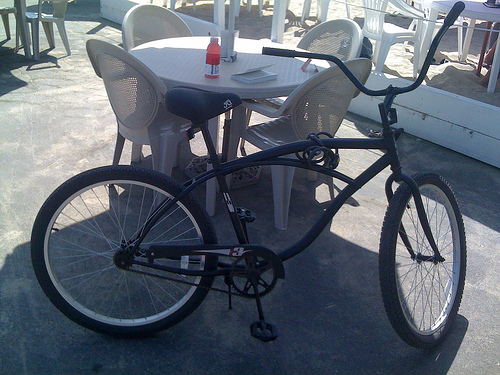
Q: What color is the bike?
A: Black.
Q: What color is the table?
A: White.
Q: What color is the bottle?
A: Pink.